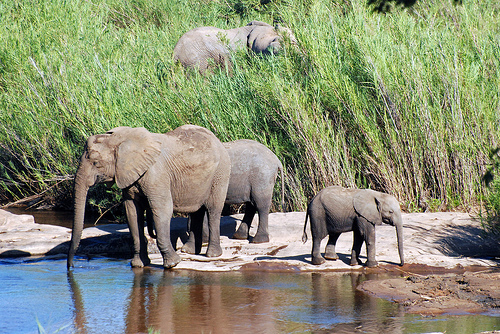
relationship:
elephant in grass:
[171, 16, 286, 76] [5, 8, 500, 226]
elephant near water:
[295, 174, 416, 282] [9, 251, 496, 333]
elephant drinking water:
[49, 115, 242, 271] [9, 251, 496, 333]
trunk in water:
[50, 169, 100, 266] [9, 251, 496, 333]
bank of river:
[0, 223, 494, 293] [9, 251, 496, 333]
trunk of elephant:
[388, 218, 416, 269] [295, 174, 416, 282]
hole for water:
[9, 251, 496, 333] [0, 251, 499, 334]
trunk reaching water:
[50, 169, 100, 266] [9, 251, 496, 333]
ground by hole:
[5, 200, 500, 268] [9, 251, 496, 333]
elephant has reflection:
[49, 115, 242, 271] [122, 251, 274, 332]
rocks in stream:
[352, 246, 499, 322] [1, 237, 293, 333]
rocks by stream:
[6, 204, 63, 251] [1, 237, 293, 333]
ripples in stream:
[6, 262, 272, 333] [1, 237, 293, 333]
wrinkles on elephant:
[138, 128, 210, 192] [49, 115, 242, 271]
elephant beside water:
[295, 174, 416, 282] [9, 251, 496, 333]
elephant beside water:
[49, 115, 242, 271] [9, 251, 496, 333]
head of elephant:
[46, 118, 162, 203] [49, 115, 242, 271]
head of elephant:
[243, 17, 305, 69] [171, 16, 286, 76]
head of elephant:
[363, 185, 404, 230] [295, 174, 416, 282]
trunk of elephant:
[50, 169, 100, 266] [49, 115, 242, 271]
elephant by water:
[295, 174, 416, 282] [9, 251, 496, 333]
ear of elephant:
[352, 190, 385, 233] [295, 174, 416, 282]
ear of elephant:
[247, 26, 273, 58] [171, 16, 286, 76]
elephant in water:
[49, 115, 242, 271] [9, 251, 496, 333]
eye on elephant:
[87, 159, 101, 170] [49, 115, 242, 271]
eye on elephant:
[385, 208, 393, 215] [295, 174, 416, 282]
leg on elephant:
[360, 228, 383, 270] [295, 174, 416, 282]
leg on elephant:
[113, 202, 153, 274] [49, 115, 242, 271]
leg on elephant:
[142, 206, 185, 272] [49, 115, 242, 271]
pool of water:
[9, 251, 496, 333] [3, 250, 399, 332]